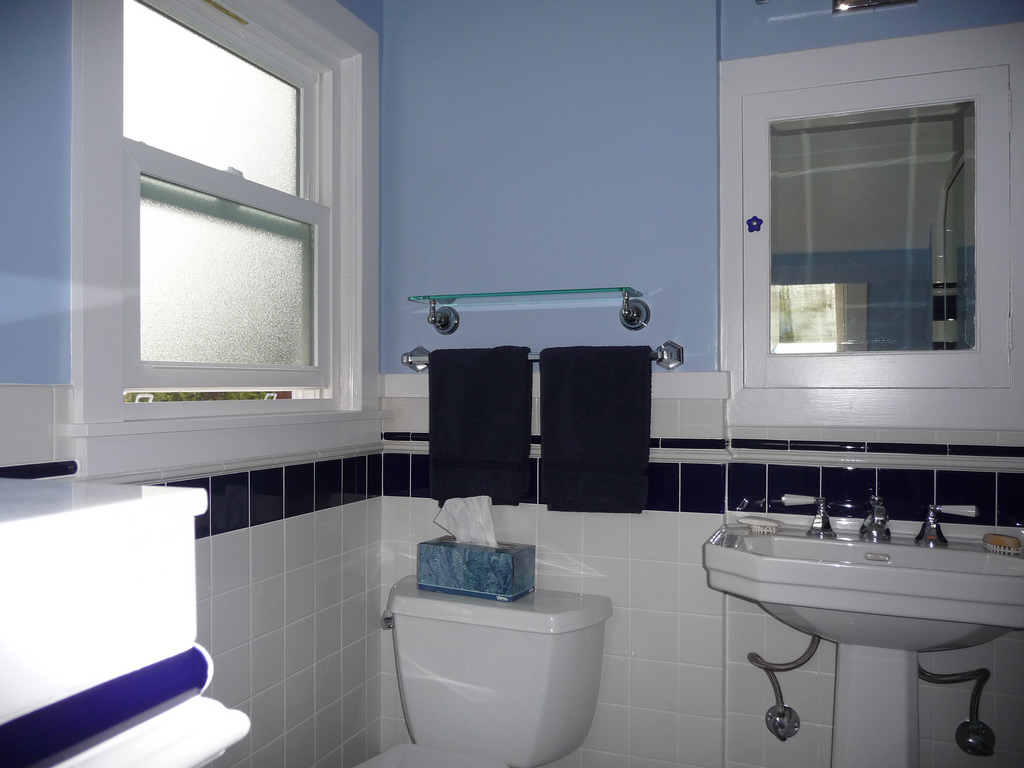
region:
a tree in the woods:
[247, 507, 282, 594]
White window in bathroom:
[67, 2, 384, 481]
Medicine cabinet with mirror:
[713, 17, 1020, 441]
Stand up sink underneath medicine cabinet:
[704, 485, 1018, 767]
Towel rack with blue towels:
[403, 337, 689, 525]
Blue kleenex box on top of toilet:
[410, 492, 540, 609]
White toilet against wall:
[347, 574, 610, 767]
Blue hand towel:
[424, 346, 536, 511]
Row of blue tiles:
[383, 435, 1023, 530]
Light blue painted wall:
[2, 1, 1023, 391]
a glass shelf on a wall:
[412, 270, 654, 335]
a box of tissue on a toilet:
[408, 516, 549, 594]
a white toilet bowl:
[358, 592, 600, 766]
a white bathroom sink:
[703, 510, 1008, 660]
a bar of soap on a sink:
[975, 526, 1020, 562]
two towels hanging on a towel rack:
[403, 338, 673, 504]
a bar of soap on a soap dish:
[974, 526, 1020, 558]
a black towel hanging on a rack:
[539, 346, 660, 518]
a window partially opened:
[86, 364, 349, 426]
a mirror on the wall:
[712, 247, 1020, 410]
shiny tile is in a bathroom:
[285, 462, 317, 514]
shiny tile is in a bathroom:
[253, 518, 289, 566]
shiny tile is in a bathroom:
[281, 512, 313, 566]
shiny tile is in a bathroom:
[310, 506, 343, 563]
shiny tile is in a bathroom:
[383, 496, 409, 548]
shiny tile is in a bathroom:
[651, 468, 680, 511]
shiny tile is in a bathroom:
[679, 462, 727, 511]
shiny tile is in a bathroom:
[727, 459, 765, 510]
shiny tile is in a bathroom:
[765, 462, 824, 514]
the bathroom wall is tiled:
[386, 367, 1022, 766]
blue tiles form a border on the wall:
[375, 414, 1021, 544]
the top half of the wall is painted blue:
[389, 13, 712, 367]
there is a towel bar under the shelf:
[402, 338, 681, 384]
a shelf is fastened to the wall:
[394, 288, 650, 324]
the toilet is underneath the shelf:
[348, 575, 608, 766]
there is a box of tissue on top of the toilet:
[402, 500, 538, 605]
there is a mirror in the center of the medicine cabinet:
[721, 66, 993, 355]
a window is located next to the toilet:
[87, 4, 404, 470]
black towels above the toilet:
[416, 332, 660, 513]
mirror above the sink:
[764, 115, 970, 351]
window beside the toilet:
[108, 3, 344, 412]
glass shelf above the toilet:
[408, 281, 652, 336]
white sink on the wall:
[726, 496, 1014, 678]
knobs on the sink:
[778, 477, 990, 551]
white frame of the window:
[67, 3, 385, 474]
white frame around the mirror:
[714, 32, 1013, 441]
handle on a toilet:
[371, 595, 400, 640]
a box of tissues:
[407, 493, 538, 608]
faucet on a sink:
[849, 496, 894, 551]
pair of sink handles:
[769, 484, 986, 564]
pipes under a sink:
[735, 630, 988, 728]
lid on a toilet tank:
[387, 582, 607, 646]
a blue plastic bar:
[6, 623, 207, 754]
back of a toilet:
[387, 608, 619, 763]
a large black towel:
[425, 349, 537, 518]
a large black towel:
[533, 341, 655, 522]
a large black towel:
[425, 338, 531, 504]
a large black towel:
[533, 346, 650, 506]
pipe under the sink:
[915, 646, 986, 726]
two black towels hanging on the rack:
[405, 342, 669, 517]